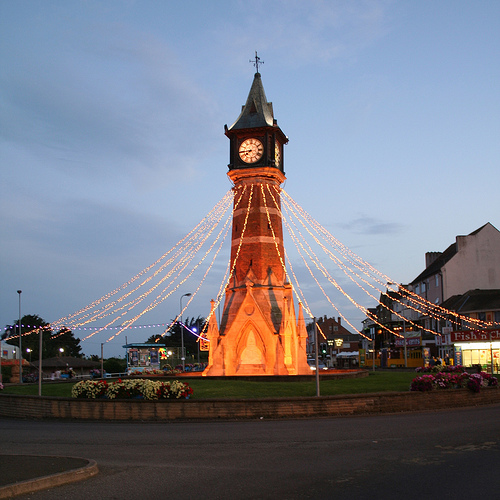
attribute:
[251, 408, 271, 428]
gradd — part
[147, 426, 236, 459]
pavement — part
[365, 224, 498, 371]
house — part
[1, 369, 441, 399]
grass — part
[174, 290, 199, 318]
cloud — part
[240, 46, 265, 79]
steeple — black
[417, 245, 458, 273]
roof — black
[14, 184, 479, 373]
lights — Christmas